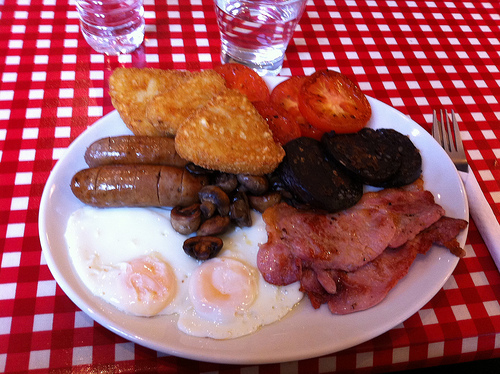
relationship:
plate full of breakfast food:
[38, 74, 470, 365] [172, 93, 286, 176]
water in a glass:
[216, 3, 298, 64] [213, 2, 307, 78]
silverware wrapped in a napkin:
[432, 107, 470, 173] [454, 163, 499, 269]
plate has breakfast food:
[38, 74, 470, 365] [75, 71, 473, 340]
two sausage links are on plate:
[73, 134, 201, 208] [38, 74, 470, 365]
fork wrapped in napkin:
[432, 107, 470, 173] [454, 163, 499, 269]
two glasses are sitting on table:
[75, 1, 308, 77] [0, 0, 499, 370]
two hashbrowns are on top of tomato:
[108, 61, 287, 177] [210, 61, 268, 103]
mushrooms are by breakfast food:
[171, 159, 280, 260] [172, 93, 286, 176]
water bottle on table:
[76, 0, 148, 56] [0, 0, 499, 370]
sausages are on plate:
[73, 134, 201, 208] [38, 74, 470, 365]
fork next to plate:
[432, 107, 470, 173] [38, 74, 470, 365]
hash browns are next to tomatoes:
[108, 61, 287, 177] [214, 59, 372, 142]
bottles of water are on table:
[75, 1, 308, 77] [0, 0, 499, 370]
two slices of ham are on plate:
[259, 176, 468, 319] [38, 74, 470, 365]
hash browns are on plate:
[108, 61, 287, 177] [38, 74, 470, 365]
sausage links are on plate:
[73, 134, 201, 208] [38, 74, 470, 365]